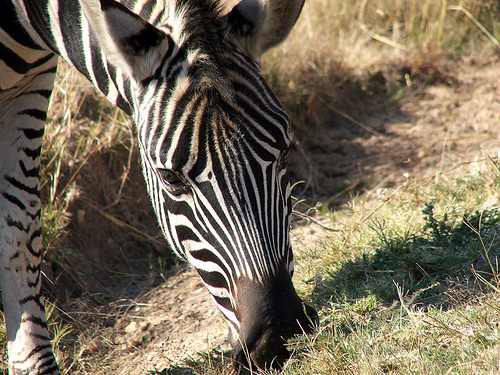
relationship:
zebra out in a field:
[3, 1, 320, 374] [0, 0, 499, 374]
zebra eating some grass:
[3, 1, 320, 374] [161, 169, 499, 374]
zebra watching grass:
[3, 1, 320, 374] [161, 169, 499, 374]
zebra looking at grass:
[3, 1, 320, 374] [161, 169, 499, 374]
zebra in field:
[3, 1, 320, 374] [0, 0, 499, 374]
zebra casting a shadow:
[3, 1, 320, 374] [306, 217, 499, 309]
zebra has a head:
[3, 1, 320, 374] [78, 0, 319, 375]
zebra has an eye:
[3, 1, 320, 374] [156, 167, 182, 191]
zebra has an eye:
[3, 1, 320, 374] [280, 140, 293, 164]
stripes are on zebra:
[202, 196, 225, 240] [3, 1, 320, 374]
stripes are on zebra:
[153, 108, 195, 144] [3, 1, 320, 374]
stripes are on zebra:
[243, 84, 269, 126] [3, 1, 320, 374]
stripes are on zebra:
[31, 6, 79, 35] [3, 1, 320, 374]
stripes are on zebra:
[5, 173, 40, 213] [3, 1, 320, 374]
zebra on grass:
[3, 1, 320, 374] [161, 169, 499, 374]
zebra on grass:
[3, 1, 320, 374] [0, 1, 499, 374]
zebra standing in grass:
[3, 1, 320, 374] [161, 169, 499, 374]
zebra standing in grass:
[3, 1, 320, 374] [0, 1, 499, 374]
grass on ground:
[161, 169, 499, 374] [0, 64, 499, 371]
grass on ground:
[0, 1, 499, 374] [0, 64, 499, 371]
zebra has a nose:
[3, 1, 320, 374] [235, 309, 320, 370]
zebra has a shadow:
[3, 1, 320, 374] [306, 217, 499, 309]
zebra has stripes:
[3, 1, 320, 374] [153, 108, 195, 144]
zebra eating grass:
[3, 1, 320, 374] [161, 169, 499, 374]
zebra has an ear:
[3, 1, 320, 374] [102, 2, 173, 80]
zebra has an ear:
[3, 1, 320, 374] [233, 3, 304, 52]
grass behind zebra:
[294, 1, 498, 80] [3, 1, 320, 374]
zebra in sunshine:
[3, 1, 320, 374] [317, 77, 499, 203]